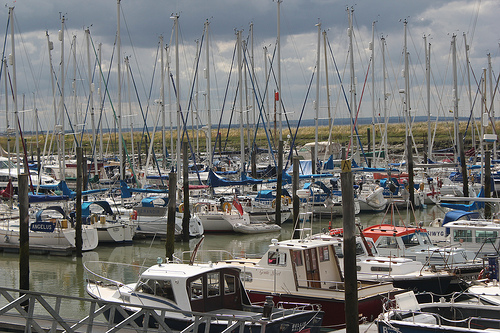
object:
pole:
[75, 146, 84, 256]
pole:
[16, 172, 32, 312]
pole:
[166, 170, 177, 257]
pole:
[182, 140, 191, 243]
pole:
[275, 139, 284, 223]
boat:
[1, 206, 99, 253]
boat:
[136, 202, 204, 241]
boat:
[223, 188, 293, 224]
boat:
[78, 255, 323, 332]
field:
[2, 119, 499, 150]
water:
[4, 248, 154, 270]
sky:
[2, 0, 498, 112]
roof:
[365, 224, 426, 237]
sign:
[30, 220, 55, 233]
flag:
[275, 89, 280, 100]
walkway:
[1, 282, 271, 331]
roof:
[139, 259, 236, 279]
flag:
[232, 198, 243, 216]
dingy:
[231, 219, 283, 236]